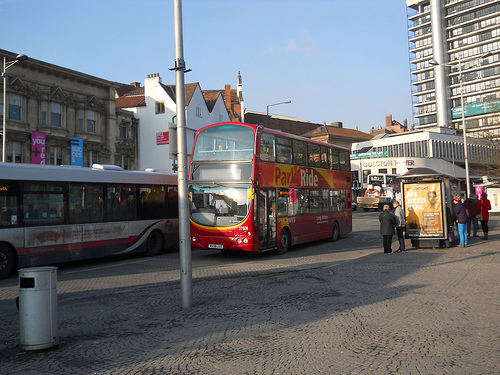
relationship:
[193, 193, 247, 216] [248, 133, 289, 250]
window of bus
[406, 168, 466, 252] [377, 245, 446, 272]
bus stop on sidewalk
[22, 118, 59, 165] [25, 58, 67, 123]
banner on building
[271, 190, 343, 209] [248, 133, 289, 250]
windows on bus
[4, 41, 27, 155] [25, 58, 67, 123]
streetlight by building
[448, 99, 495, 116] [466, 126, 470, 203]
sign on pole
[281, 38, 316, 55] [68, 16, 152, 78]
cloud in sky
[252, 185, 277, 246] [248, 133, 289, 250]
door on bus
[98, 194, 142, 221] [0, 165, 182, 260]
people are standing in bus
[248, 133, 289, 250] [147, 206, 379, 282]
bus on road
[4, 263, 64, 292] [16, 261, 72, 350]
lid of trashcan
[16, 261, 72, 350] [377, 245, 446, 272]
trashcan on sidewalk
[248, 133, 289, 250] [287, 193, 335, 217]
bus to carry people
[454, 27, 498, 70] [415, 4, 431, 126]
balconies on building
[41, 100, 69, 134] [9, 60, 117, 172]
window on building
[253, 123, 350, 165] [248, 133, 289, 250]
top of bus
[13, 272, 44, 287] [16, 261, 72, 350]
opening of trashcan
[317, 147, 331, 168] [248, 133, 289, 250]
window on bus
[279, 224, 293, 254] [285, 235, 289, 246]
tire of bus black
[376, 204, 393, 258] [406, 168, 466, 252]
person standing by bus stop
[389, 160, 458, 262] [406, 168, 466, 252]
side of bus stop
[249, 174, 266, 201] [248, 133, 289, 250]
mirror on bus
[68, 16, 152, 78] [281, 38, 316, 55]
sky has a cloud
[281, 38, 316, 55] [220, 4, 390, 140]
cloud in sky